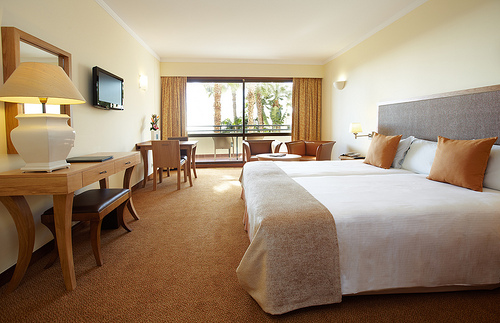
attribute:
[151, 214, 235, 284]
carpet — brown, clean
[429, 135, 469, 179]
pillow — white, orange, brown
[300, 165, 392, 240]
bed — white, made, nice, brown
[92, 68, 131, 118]
tv — off, black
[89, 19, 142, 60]
wall — white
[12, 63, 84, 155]
lamp — on, red, beige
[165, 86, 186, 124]
curtains — open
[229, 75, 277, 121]
door — glass